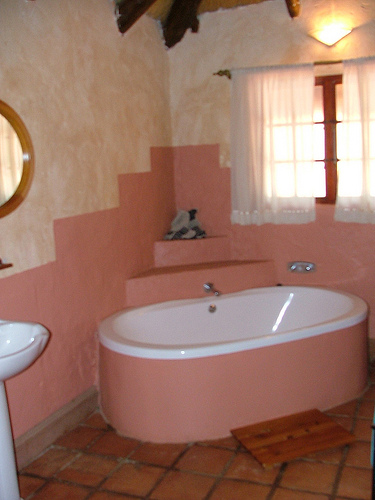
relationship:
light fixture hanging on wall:
[298, 17, 350, 48] [168, 0, 373, 359]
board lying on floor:
[229, 406, 360, 471] [14, 362, 374, 498]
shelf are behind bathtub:
[124, 232, 279, 309] [97, 284, 368, 445]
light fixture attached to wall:
[298, 17, 360, 48] [168, 0, 373, 359]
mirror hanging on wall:
[3, 97, 37, 217] [3, 0, 167, 446]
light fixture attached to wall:
[298, 17, 350, 48] [168, 0, 373, 359]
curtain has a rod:
[229, 55, 375, 223] [213, 57, 374, 83]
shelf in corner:
[124, 230, 279, 309] [158, 6, 200, 305]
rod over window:
[213, 57, 374, 83] [235, 57, 373, 214]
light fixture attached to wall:
[298, 17, 350, 48] [164, 6, 238, 144]